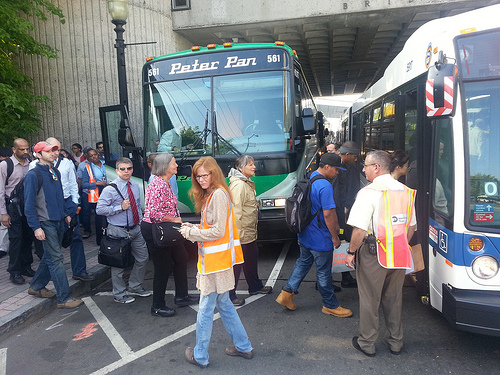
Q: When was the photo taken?
A: Daytime.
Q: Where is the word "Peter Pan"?
A: Left bus.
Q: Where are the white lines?
A: Pavement.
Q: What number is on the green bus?
A: 561.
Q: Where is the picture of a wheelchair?
A: White bus.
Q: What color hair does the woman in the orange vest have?
A: Red.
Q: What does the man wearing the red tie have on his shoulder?
A: Bag.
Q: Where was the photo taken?
A: At a bus station.